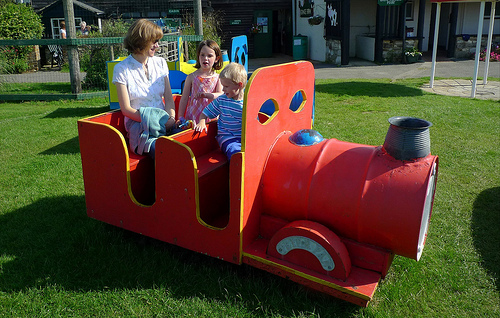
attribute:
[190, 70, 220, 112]
dress — pink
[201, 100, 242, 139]
shirt — blue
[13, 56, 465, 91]
road — paved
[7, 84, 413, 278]
grass — green, well cared for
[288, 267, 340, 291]
color — yellow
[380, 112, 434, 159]
spout — small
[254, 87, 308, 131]
design — cut out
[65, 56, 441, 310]
train — toy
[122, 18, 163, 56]
hair — short, brown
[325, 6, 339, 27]
animal — small, white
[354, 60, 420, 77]
color — gray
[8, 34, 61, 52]
post — green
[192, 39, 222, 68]
hair — red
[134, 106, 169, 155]
sweater — blue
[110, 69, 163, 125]
arm — woman's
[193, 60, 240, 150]
boy — striped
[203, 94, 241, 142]
shirt — blue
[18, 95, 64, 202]
grass — green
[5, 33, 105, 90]
fence — green, grey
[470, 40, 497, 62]
flowers — cluster, pink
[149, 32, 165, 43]
glasses — dark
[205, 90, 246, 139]
shirt — blue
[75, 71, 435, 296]
train — toy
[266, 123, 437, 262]
tank — red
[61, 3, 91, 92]
post — tree, brown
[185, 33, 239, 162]
kid — little blond 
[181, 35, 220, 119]
girl — little red haired 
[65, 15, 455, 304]
train — red wagon , black ,  red wagno, red wooden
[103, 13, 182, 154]
woman — shirt 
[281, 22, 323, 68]
can — round green trash 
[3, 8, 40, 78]
bushes — green 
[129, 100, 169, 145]
sweater — blue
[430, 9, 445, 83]
poles — white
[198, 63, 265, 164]
boy — blond hair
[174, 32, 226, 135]
girl — sitting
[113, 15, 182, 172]
woman — sitting, holding 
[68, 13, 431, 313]
train — red wooden